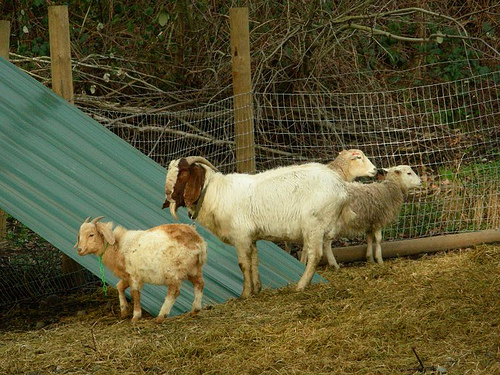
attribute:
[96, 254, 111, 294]
chain — green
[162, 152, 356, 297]
goat — white, brown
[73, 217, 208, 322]
baby goat — tan, white, smallest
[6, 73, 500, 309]
fence — wired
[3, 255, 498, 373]
grass — green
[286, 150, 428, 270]
sheep — white, smaller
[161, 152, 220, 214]
head — brown, white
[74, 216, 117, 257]
head — white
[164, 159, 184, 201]
face — brown, white